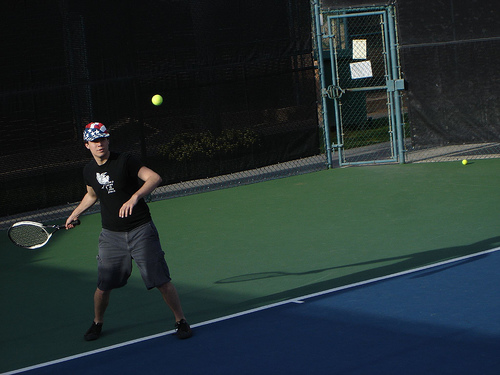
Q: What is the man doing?
A: Playing tennis.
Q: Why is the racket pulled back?
A: To hit the ball.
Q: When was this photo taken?
A: At night.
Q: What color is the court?
A: Blue and green.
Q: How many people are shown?
A: 1.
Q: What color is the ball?
A: Neon green.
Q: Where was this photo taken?
A: On a tennis court.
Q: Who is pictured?
A: A man that is playing tennis.